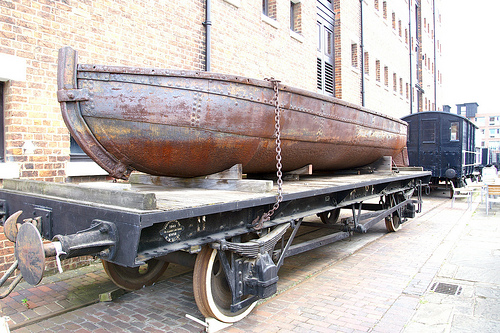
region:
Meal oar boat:
[52, 46, 412, 176]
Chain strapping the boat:
[263, 74, 287, 206]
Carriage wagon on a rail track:
[1, 176, 445, 325]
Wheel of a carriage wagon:
[178, 243, 285, 331]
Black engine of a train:
[396, 104, 486, 192]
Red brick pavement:
[311, 234, 386, 315]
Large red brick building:
[260, 31, 439, 105]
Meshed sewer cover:
[424, 271, 476, 309]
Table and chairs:
[447, 177, 499, 216]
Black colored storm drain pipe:
[355, 5, 367, 104]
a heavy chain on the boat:
[269, 92, 294, 206]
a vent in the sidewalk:
[429, 267, 477, 311]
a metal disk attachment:
[13, 222, 51, 287]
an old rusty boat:
[85, 62, 405, 170]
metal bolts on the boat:
[191, 90, 202, 133]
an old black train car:
[406, 109, 478, 182]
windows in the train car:
[410, 117, 467, 145]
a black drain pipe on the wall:
[203, 5, 220, 70]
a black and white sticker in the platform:
[166, 221, 188, 242]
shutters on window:
[319, 80, 334, 90]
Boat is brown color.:
[51, 58, 381, 173]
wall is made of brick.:
[76, 6, 206, 48]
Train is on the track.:
[26, 80, 389, 332]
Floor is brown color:
[298, 270, 363, 325]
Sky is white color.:
[446, 11, 498, 83]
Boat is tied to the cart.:
[186, 80, 301, 230]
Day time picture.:
[25, 32, 480, 304]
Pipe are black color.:
[180, 6, 265, 76]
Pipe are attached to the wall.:
[180, 1, 270, 101]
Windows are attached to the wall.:
[343, 8, 424, 94]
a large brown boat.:
[49, 43, 412, 174]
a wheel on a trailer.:
[174, 236, 279, 331]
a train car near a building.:
[390, 104, 487, 188]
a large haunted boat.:
[45, 41, 417, 191]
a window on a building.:
[283, 0, 310, 52]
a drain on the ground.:
[415, 271, 467, 300]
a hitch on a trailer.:
[5, 203, 114, 293]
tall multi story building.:
[434, 93, 496, 169]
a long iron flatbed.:
[2, 151, 452, 281]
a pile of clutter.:
[459, 172, 497, 217]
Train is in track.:
[58, 57, 480, 310]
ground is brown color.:
[313, 273, 387, 310]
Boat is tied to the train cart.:
[91, 88, 413, 215]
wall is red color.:
[56, 10, 171, 46]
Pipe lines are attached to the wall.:
[195, 5, 240, 65]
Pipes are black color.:
[187, 7, 227, 67]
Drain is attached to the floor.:
[417, 265, 467, 305]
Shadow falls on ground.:
[13, 283, 150, 329]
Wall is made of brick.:
[106, 11, 173, 49]